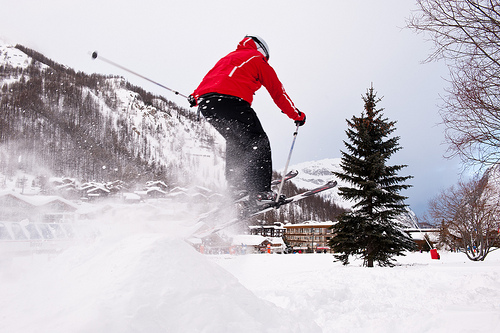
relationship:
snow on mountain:
[76, 188, 197, 290] [31, 52, 122, 145]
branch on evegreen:
[326, 171, 379, 196] [348, 88, 443, 232]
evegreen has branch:
[348, 88, 443, 232] [326, 171, 379, 196]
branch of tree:
[326, 171, 379, 196] [338, 109, 398, 233]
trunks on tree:
[438, 217, 499, 266] [338, 109, 398, 233]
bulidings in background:
[283, 201, 382, 271] [292, 184, 498, 290]